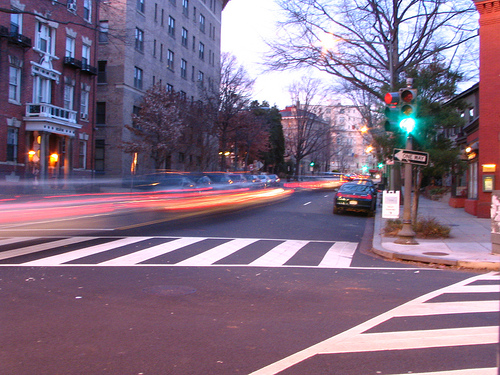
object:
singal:
[376, 102, 441, 165]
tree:
[257, 0, 480, 202]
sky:
[220, 0, 264, 39]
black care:
[330, 180, 376, 216]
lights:
[360, 120, 379, 159]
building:
[294, 97, 379, 178]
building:
[93, 1, 226, 176]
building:
[280, 106, 330, 174]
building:
[448, 0, 498, 217]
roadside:
[288, 307, 498, 374]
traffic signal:
[382, 88, 427, 148]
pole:
[397, 137, 416, 243]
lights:
[24, 149, 64, 171]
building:
[3, 20, 98, 163]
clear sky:
[218, 1, 436, 72]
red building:
[456, 1, 498, 216]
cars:
[2, 169, 303, 264]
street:
[3, 346, 163, 374]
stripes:
[6, 238, 131, 281]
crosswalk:
[7, 222, 499, 274]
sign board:
[383, 143, 430, 171]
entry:
[42, 133, 71, 167]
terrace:
[34, 69, 92, 126]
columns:
[28, 75, 44, 104]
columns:
[41, 75, 53, 110]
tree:
[122, 82, 189, 171]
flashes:
[0, 160, 340, 219]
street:
[53, 215, 298, 240]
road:
[1, 307, 265, 374]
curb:
[372, 170, 499, 266]